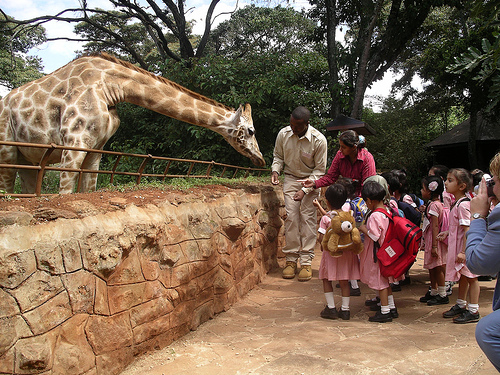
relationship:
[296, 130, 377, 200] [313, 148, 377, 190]
black-haired woman in pink shirt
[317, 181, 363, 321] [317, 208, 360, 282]
girl wearing dress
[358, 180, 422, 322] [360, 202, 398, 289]
girl wearing dress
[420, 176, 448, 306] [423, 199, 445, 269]
girl wearing dress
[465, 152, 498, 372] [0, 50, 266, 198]
man taking photo of brown/white giraffe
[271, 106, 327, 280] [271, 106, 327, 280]
black man a male tour black man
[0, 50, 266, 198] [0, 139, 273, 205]
brown/white giraffe over fence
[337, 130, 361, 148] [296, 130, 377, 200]
head of black-haired woman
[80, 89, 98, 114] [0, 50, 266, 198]
spot on brown/white giraffe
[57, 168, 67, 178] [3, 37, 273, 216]
spot on giraffe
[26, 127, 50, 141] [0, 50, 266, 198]
spot on brown/white giraffe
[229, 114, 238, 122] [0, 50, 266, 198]
spot on brown/white giraffe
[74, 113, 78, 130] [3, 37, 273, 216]
spot on giraffe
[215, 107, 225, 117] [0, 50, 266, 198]
spot on brown/white giraffe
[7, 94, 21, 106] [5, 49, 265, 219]
spot on giraffe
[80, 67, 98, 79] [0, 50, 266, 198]
spot on brown/white giraffe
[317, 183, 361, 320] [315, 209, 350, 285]
girl in dress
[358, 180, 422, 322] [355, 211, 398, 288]
girl in dress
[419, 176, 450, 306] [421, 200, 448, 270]
girl in dress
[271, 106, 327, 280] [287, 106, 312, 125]
black man has hair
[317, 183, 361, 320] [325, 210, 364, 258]
girl wearing a backpack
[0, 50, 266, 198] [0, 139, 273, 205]
brown/white giraffe standing behind fence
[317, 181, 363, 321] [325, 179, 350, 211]
girl has black hair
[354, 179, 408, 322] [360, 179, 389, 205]
girl has short hair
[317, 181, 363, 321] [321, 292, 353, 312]
girl wearing white socks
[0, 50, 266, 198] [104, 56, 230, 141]
brown/white giraffe has a long neck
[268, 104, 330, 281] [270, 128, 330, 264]
black man in khaki uniform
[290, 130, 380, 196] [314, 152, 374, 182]
black-haired woman in pink shirt